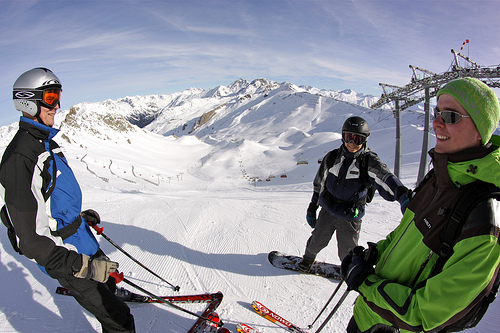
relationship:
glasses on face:
[430, 104, 470, 128] [428, 86, 481, 155]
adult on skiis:
[337, 75, 500, 333] [232, 300, 321, 330]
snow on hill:
[153, 156, 183, 191] [106, 130, 309, 191]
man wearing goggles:
[3, 63, 135, 330] [20, 86, 64, 112]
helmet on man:
[10, 65, 62, 117] [2, 61, 155, 331]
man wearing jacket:
[3, 63, 135, 330] [1, 115, 111, 295]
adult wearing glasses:
[337, 75, 500, 333] [434, 106, 469, 123]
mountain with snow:
[76, 80, 288, 221] [65, 95, 254, 231]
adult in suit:
[358, 42, 499, 178] [323, 170, 466, 328]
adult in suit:
[301, 102, 399, 202] [305, 135, 403, 249]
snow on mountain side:
[96, 128, 150, 166] [70, 75, 159, 160]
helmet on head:
[12, 67, 62, 118] [3, 55, 70, 145]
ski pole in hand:
[92, 230, 186, 293] [59, 220, 133, 316]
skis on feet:
[119, 266, 228, 313] [107, 286, 159, 331]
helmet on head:
[327, 106, 383, 173] [334, 120, 384, 176]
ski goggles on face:
[335, 130, 365, 150] [336, 122, 362, 154]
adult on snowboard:
[297, 115, 413, 272] [262, 243, 357, 293]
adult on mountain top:
[297, 115, 413, 272] [200, 199, 330, 305]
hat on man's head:
[445, 85, 498, 139] [410, 69, 499, 193]